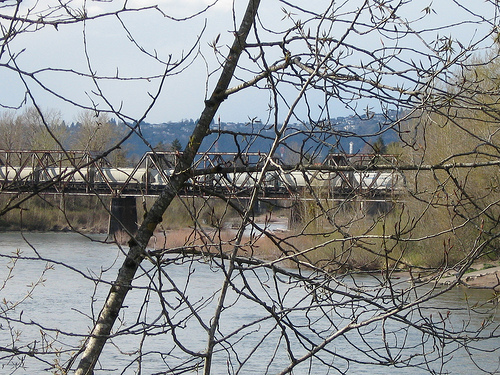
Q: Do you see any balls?
A: No, there are no balls.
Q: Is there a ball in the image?
A: No, there are no balls.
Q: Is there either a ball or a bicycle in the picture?
A: No, there are no balls or bicycles.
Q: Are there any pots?
A: No, there are no pots.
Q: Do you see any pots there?
A: No, there are no pots.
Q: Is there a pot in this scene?
A: No, there are no pots.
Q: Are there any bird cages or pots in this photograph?
A: No, there are no pots or bird cages.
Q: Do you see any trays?
A: No, there are no trays.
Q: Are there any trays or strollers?
A: No, there are no trays or strollers.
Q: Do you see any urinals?
A: No, there are no urinals.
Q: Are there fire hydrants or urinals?
A: No, there are no urinals or fire hydrants.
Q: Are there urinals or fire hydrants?
A: No, there are no urinals or fire hydrants.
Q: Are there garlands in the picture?
A: No, there are no garlands.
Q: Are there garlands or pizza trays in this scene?
A: No, there are no garlands or pizza trays.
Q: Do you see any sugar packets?
A: No, there are no sugar packets.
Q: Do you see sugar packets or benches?
A: No, there are no sugar packets or benches.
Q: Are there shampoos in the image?
A: No, there are no shampoos.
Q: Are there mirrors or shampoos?
A: No, there are no shampoos or mirrors.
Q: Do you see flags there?
A: No, there are no flags.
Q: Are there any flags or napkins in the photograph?
A: No, there are no flags or napkins.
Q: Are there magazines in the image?
A: No, there are no magazines.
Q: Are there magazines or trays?
A: No, there are no magazines or trays.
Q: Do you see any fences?
A: No, there are no fences.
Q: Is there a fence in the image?
A: No, there are no fences.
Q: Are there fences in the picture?
A: No, there are no fences.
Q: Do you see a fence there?
A: No, there are no fences.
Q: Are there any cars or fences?
A: No, there are no fences or cars.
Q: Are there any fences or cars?
A: No, there are no fences or cars.